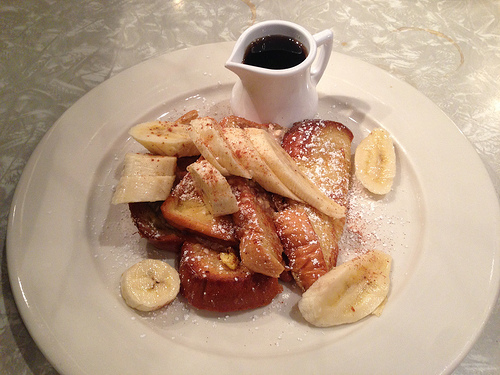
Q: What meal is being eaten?
A: Breakfast.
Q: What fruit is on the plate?
A: Banana.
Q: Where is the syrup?
A: In a pitcher.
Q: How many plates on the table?
A: One.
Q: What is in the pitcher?
A: Syrup.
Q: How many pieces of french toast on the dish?
A: Three.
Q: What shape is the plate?
A: Round.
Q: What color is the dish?
A: White.